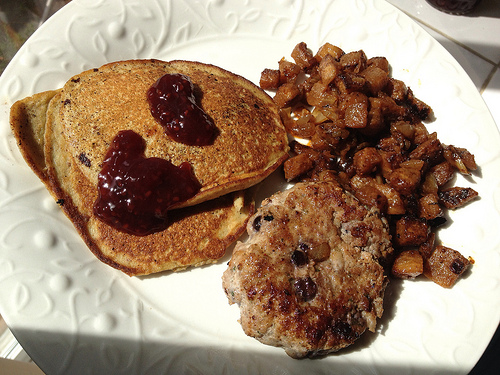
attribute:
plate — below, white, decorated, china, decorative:
[0, 0, 499, 373]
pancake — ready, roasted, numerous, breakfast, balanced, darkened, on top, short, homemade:
[60, 53, 288, 202]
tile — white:
[395, 10, 496, 93]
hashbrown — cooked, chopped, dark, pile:
[335, 85, 370, 130]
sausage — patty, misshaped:
[231, 183, 390, 359]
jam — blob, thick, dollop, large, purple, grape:
[143, 74, 220, 145]